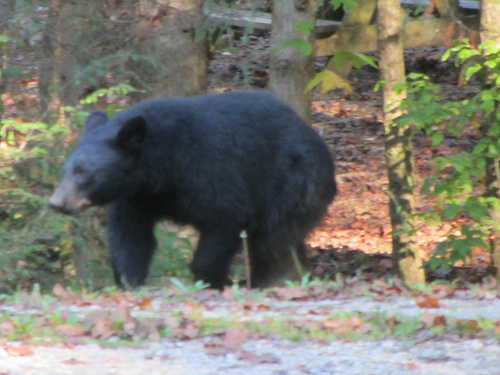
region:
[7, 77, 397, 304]
large furry black bear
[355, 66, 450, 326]
shadow of leaves in a forest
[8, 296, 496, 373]
gravel dirt road with dead leaves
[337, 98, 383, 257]
dead leaves on the forest floor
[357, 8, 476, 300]
small brown thin tree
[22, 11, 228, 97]
very large brown tree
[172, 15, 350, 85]
large recreational camper vehicle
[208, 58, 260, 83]
recreational vehicle tire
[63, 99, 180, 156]
two black bear ears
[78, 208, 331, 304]
four large black bear legs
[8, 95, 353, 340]
the bear is black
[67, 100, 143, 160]
the bear has two ears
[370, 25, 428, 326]
the tree branch is brown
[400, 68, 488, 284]
the leaves are green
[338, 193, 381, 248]
dry leaves on the ground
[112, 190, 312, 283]
the bear has four feet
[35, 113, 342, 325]
the bear is looking at his right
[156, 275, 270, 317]
the grass is green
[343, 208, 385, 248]
dry leaves are brown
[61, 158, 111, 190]
bear's eyes are open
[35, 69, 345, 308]
Medium sized brown bear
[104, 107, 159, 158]
Furry black ear of bear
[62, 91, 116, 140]
Furry black ear of bear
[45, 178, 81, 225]
Large brown bear nose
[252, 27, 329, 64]
Green tree leaf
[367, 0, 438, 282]
Brown tree trunk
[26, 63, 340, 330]
Medium sized bear with brown fur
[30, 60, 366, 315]
Medium sized bear in the forest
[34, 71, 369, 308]
Bear standing near trees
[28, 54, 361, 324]
Medium sized bear walking in the forest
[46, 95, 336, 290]
the bear has black fur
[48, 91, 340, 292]
the bear is walking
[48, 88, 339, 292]
the bear is in the woods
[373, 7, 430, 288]
a tree trunk is in the sun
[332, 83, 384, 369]
brown leaves are on the ground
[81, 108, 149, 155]
the bear's ears are back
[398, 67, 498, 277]
a bush is in the forrest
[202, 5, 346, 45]
a cabin is behind the bear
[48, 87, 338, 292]
big bear is black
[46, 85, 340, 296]
bear is standing on ground.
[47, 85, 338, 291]
Black bear is huge.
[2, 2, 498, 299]
bear is standing in the woods.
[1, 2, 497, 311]
bear is walking through a forest.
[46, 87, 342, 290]
big bear.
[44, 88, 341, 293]
big black bear.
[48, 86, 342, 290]
bear stands on four legs.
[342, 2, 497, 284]
leaves are green on trees.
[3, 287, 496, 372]
leaves are brown on ground.